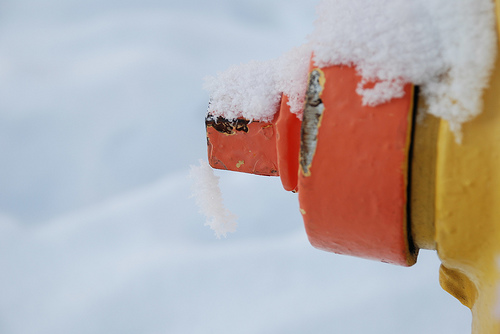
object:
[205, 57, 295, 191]
screw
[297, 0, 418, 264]
fitting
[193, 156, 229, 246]
snow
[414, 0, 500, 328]
body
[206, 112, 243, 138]
rust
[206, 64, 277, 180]
end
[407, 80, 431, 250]
threads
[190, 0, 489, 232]
snow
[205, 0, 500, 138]
snow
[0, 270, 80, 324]
snow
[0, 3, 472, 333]
ground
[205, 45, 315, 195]
tip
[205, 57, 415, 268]
orange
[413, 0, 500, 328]
yellow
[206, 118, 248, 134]
hole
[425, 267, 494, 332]
bottom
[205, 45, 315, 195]
part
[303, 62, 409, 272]
part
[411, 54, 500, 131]
part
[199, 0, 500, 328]
fire hydrant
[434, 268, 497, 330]
part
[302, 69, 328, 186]
chipped paint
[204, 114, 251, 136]
chipped paint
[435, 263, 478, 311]
corner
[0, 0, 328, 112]
snow patch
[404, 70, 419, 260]
seamline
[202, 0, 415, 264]
cap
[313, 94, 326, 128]
speckle